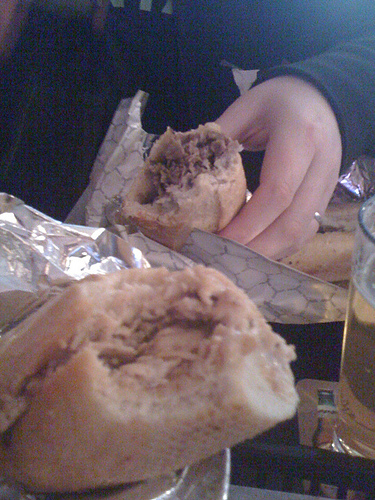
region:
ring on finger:
[312, 211, 324, 224]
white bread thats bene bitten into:
[195, 379, 270, 432]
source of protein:
[133, 313, 202, 374]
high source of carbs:
[39, 388, 227, 453]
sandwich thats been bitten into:
[0, 266, 300, 439]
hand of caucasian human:
[219, 78, 330, 258]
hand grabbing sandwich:
[122, 90, 327, 261]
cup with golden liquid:
[325, 196, 374, 463]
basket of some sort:
[245, 444, 367, 492]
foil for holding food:
[189, 231, 310, 306]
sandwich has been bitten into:
[42, 263, 287, 431]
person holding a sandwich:
[118, 47, 373, 299]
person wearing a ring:
[312, 196, 330, 230]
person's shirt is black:
[4, 2, 355, 237]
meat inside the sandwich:
[0, 290, 263, 415]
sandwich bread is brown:
[3, 274, 311, 464]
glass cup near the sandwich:
[324, 187, 372, 467]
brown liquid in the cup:
[330, 276, 372, 464]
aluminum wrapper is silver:
[2, 188, 139, 291]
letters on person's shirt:
[107, 0, 179, 38]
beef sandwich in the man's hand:
[121, 115, 248, 237]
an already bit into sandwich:
[0, 267, 299, 495]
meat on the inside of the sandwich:
[104, 294, 248, 401]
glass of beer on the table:
[343, 186, 374, 464]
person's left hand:
[199, 62, 355, 265]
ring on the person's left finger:
[309, 209, 325, 225]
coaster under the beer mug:
[296, 368, 343, 449]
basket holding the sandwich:
[226, 447, 372, 498]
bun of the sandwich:
[18, 353, 291, 482]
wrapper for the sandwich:
[0, 186, 177, 310]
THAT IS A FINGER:
[214, 100, 262, 131]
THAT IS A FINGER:
[243, 118, 292, 230]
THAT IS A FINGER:
[290, 173, 322, 231]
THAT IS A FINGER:
[307, 192, 325, 245]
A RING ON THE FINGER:
[313, 206, 323, 224]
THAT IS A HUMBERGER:
[132, 121, 239, 233]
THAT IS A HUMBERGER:
[28, 264, 254, 459]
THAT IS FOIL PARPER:
[32, 216, 73, 282]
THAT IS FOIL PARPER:
[106, 100, 140, 183]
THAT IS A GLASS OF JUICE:
[340, 233, 373, 440]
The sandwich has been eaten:
[11, 283, 286, 463]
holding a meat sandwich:
[50, 290, 285, 440]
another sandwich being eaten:
[138, 93, 293, 236]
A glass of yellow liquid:
[331, 241, 367, 450]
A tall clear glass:
[337, 202, 370, 470]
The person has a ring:
[309, 189, 326, 232]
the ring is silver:
[302, 197, 330, 232]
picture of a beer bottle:
[308, 377, 356, 483]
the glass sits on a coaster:
[301, 370, 369, 465]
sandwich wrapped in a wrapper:
[31, 141, 236, 285]